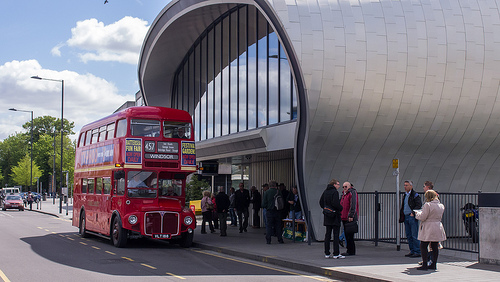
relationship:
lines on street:
[86, 230, 136, 279] [11, 214, 168, 275]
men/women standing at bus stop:
[317, 171, 447, 271] [177, 159, 499, 280]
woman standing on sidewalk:
[319, 167, 397, 245] [304, 233, 386, 280]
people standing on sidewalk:
[189, 159, 449, 269] [199, 182, 499, 279]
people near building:
[196, 175, 296, 243] [128, 11, 473, 192]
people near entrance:
[196, 175, 296, 243] [202, 156, 253, 205]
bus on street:
[68, 101, 200, 249] [3, 200, 367, 280]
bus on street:
[68, 101, 200, 249] [0, 201, 167, 278]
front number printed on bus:
[137, 132, 165, 160] [63, 112, 211, 248]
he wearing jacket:
[335, 178, 362, 256] [329, 169, 364, 254]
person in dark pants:
[319, 176, 345, 258] [320, 222, 338, 256]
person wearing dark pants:
[398, 175, 428, 257] [402, 212, 423, 252]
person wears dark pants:
[316, 175, 343, 260] [317, 214, 344, 266]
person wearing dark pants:
[245, 181, 273, 243] [248, 201, 265, 228]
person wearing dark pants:
[229, 179, 254, 231] [238, 206, 248, 226]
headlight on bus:
[129, 211, 140, 229] [47, 104, 204, 244]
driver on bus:
[126, 165, 152, 195] [63, 112, 211, 248]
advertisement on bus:
[117, 133, 149, 165] [125, 136, 152, 168]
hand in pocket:
[408, 213, 413, 217] [408, 215, 415, 222]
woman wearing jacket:
[412, 188, 445, 273] [414, 196, 449, 243]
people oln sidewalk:
[180, 177, 310, 237] [192, 220, 499, 282]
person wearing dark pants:
[318, 175, 342, 263] [321, 208, 342, 258]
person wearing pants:
[202, 189, 232, 234] [200, 208, 214, 230]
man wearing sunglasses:
[339, 180, 359, 255] [340, 184, 347, 189]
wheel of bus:
[105, 217, 127, 247] [63, 112, 211, 248]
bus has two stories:
[47, 104, 204, 244] [71, 92, 195, 244]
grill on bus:
[141, 206, 186, 240] [68, 101, 200, 249]